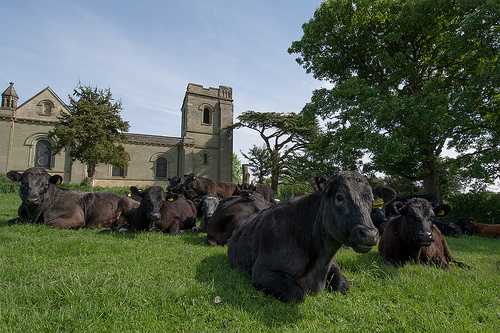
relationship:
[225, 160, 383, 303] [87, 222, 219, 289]
cow laying in field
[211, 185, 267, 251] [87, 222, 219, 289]
cow laying in field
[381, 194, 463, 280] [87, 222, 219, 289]
cow laying in field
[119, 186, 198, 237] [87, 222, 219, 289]
cow laying in field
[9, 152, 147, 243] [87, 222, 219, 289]
cow laying in field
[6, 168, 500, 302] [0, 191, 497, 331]
cattles laying in grass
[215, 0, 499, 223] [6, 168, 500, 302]
tree next to cattles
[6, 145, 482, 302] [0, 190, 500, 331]
cattles on grass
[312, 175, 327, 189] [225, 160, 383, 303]
black ears of cow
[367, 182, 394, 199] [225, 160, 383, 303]
black ears of cow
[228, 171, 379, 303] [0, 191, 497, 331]
cow laying in grass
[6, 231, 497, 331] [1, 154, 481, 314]
grass surrounds cows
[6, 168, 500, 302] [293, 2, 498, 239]
cattles laying next to tree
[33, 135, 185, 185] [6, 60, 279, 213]
windows on building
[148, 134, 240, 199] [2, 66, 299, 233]
shadow on building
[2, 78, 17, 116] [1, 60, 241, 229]
temple on building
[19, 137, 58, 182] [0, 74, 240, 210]
door on building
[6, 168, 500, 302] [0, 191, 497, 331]
cattles on grass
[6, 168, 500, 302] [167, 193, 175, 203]
cattles have tag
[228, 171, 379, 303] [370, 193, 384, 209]
cow has tag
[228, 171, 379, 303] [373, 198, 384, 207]
cow has yellow tag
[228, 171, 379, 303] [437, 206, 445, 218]
cow has tag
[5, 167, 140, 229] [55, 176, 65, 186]
cow has tag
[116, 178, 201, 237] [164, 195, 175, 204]
cow has tag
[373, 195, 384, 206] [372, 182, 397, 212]
tag in ear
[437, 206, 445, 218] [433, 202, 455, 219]
tag in ear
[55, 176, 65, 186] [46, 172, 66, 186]
tag in ear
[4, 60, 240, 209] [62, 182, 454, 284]
building behind cows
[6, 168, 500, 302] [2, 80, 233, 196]
cattles near bilding